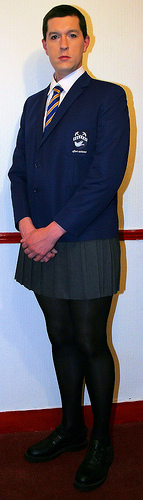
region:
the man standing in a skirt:
[7, 5, 129, 492]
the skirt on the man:
[14, 237, 120, 299]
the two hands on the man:
[19, 221, 56, 262]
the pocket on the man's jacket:
[65, 131, 93, 156]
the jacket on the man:
[7, 70, 128, 241]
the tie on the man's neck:
[44, 85, 62, 126]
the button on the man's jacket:
[34, 162, 39, 167]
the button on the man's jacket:
[33, 187, 38, 192]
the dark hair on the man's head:
[42, 4, 86, 41]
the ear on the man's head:
[81, 35, 89, 52]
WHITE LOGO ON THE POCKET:
[73, 132, 89, 154]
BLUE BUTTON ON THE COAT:
[35, 163, 39, 171]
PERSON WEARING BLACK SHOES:
[84, 461, 98, 468]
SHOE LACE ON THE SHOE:
[88, 456, 94, 462]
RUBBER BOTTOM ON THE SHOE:
[61, 448, 72, 451]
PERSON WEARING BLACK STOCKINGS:
[95, 317, 99, 350]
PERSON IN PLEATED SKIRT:
[91, 251, 118, 277]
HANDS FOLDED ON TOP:
[20, 230, 53, 250]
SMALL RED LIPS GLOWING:
[57, 55, 71, 59]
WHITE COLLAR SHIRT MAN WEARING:
[65, 77, 72, 87]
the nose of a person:
[59, 38, 66, 48]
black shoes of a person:
[23, 421, 114, 490]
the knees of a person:
[41, 325, 103, 359]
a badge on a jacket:
[73, 130, 87, 153]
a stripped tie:
[51, 86, 59, 115]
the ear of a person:
[83, 35, 88, 53]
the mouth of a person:
[58, 53, 71, 61]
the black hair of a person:
[49, 8, 77, 16]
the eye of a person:
[51, 33, 59, 41]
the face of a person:
[46, 18, 78, 69]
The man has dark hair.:
[38, 4, 91, 37]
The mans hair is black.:
[33, 3, 91, 41]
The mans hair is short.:
[32, 3, 94, 39]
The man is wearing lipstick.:
[54, 54, 72, 60]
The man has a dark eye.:
[47, 32, 60, 41]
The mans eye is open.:
[47, 31, 59, 40]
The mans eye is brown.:
[48, 34, 62, 41]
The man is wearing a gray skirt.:
[6, 212, 132, 312]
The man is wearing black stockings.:
[29, 284, 121, 427]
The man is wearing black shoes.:
[24, 419, 114, 486]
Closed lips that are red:
[57, 53, 70, 60]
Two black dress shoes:
[23, 421, 113, 491]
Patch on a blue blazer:
[72, 129, 89, 156]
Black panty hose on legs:
[36, 298, 118, 437]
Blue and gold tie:
[42, 86, 64, 131]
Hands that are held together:
[15, 216, 64, 261]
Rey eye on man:
[68, 31, 76, 38]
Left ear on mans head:
[41, 38, 46, 53]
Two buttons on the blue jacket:
[31, 161, 41, 198]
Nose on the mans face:
[59, 43, 69, 51]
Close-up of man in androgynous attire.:
[1, 1, 142, 499]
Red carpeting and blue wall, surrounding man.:
[0, 378, 31, 441]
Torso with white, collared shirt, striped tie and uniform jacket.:
[18, 76, 117, 240]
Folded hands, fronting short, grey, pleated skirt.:
[13, 209, 128, 297]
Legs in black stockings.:
[37, 294, 121, 433]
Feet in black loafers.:
[26, 430, 114, 488]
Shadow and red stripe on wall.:
[118, 122, 142, 238]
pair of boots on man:
[24, 401, 118, 493]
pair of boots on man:
[20, 400, 130, 492]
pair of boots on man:
[21, 393, 138, 491]